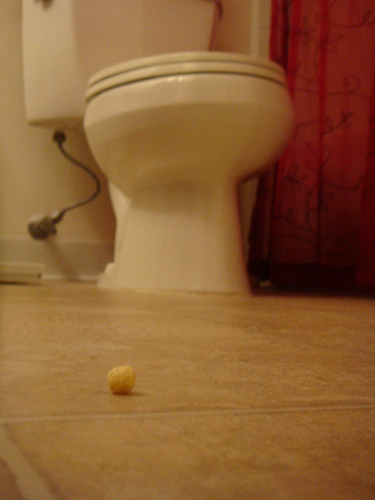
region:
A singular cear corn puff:
[100, 359, 140, 400]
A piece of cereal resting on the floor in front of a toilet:
[68, 47, 286, 401]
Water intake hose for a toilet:
[26, 129, 101, 238]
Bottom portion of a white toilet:
[80, 48, 303, 299]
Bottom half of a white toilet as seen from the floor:
[59, 45, 301, 293]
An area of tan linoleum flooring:
[142, 310, 371, 494]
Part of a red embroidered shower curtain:
[295, 11, 371, 276]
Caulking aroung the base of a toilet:
[105, 269, 258, 304]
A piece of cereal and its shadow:
[104, 357, 152, 400]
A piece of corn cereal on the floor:
[102, 360, 262, 430]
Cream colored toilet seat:
[86, 52, 292, 301]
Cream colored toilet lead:
[90, 52, 295, 67]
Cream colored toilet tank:
[21, 2, 218, 130]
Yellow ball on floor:
[106, 364, 136, 391]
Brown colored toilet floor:
[0, 285, 372, 499]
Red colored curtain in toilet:
[250, 3, 374, 289]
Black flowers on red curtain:
[283, 138, 361, 262]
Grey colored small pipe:
[24, 134, 102, 239]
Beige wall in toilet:
[2, 96, 86, 275]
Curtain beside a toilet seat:
[254, 2, 374, 291]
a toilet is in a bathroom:
[9, 5, 373, 493]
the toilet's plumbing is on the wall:
[19, 121, 103, 242]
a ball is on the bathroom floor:
[94, 360, 149, 408]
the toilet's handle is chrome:
[27, 0, 59, 11]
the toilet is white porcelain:
[16, 2, 296, 297]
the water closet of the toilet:
[17, 1, 217, 124]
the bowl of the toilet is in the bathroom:
[80, 73, 298, 308]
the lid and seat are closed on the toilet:
[81, 50, 289, 104]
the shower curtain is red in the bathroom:
[243, 0, 374, 296]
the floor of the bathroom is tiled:
[2, 279, 373, 498]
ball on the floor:
[100, 358, 141, 391]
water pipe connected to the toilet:
[16, 129, 101, 249]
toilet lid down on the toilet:
[80, 45, 288, 90]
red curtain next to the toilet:
[280, 2, 373, 300]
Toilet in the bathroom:
[18, 24, 335, 292]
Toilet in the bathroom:
[59, 52, 215, 174]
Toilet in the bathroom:
[174, 38, 295, 302]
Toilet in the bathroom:
[13, 0, 94, 124]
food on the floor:
[100, 356, 161, 407]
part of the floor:
[81, 436, 111, 461]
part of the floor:
[175, 467, 212, 492]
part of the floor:
[270, 433, 296, 458]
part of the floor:
[219, 404, 232, 425]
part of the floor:
[139, 466, 165, 490]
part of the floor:
[208, 377, 241, 404]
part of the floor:
[178, 332, 198, 362]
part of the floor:
[43, 333, 67, 358]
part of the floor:
[64, 456, 91, 471]